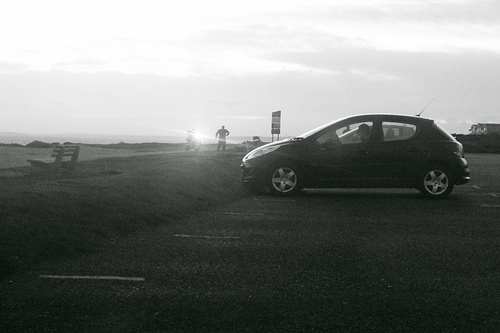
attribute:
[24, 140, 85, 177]
bench — empty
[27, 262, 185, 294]
line — white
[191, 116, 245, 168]
man — standing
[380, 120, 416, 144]
window — rear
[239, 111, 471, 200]
car — small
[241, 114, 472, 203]
black car — small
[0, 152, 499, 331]
asphalt — black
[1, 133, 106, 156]
mountains — distant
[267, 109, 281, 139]
sign — metal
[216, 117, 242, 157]
person — walking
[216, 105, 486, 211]
car — parked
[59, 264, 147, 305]
paint — faded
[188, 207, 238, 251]
paint — faded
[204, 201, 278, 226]
paint — faded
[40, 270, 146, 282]
stripe — short, white